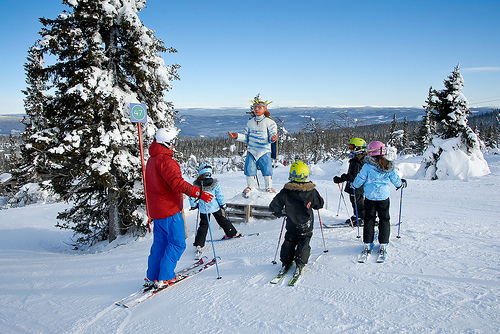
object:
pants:
[361, 197, 392, 247]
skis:
[375, 242, 391, 264]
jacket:
[350, 155, 404, 202]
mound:
[0, 143, 497, 331]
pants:
[141, 213, 189, 282]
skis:
[114, 256, 223, 310]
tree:
[17, 0, 183, 242]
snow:
[0, 133, 500, 334]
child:
[265, 155, 325, 278]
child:
[347, 140, 406, 258]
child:
[332, 146, 367, 225]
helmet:
[286, 159, 311, 184]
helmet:
[345, 136, 369, 152]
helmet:
[361, 139, 389, 158]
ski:
[285, 250, 311, 288]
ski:
[269, 253, 287, 286]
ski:
[322, 220, 384, 229]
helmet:
[152, 125, 178, 150]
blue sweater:
[349, 162, 403, 201]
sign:
[125, 99, 152, 126]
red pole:
[133, 121, 154, 232]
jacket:
[135, 140, 204, 220]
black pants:
[280, 228, 310, 270]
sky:
[1, 0, 500, 131]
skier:
[136, 125, 213, 288]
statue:
[223, 94, 285, 199]